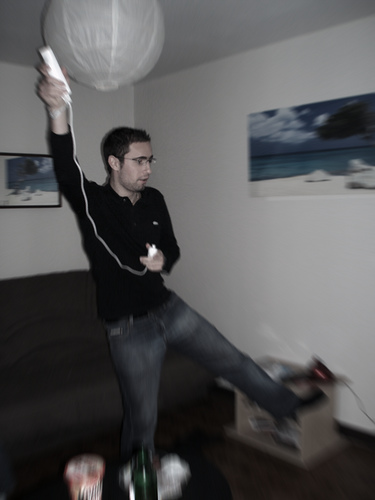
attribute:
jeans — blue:
[87, 289, 316, 486]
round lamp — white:
[39, 0, 170, 89]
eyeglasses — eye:
[115, 155, 157, 165]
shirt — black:
[43, 123, 180, 321]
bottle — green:
[129, 442, 156, 498]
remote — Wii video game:
[33, 42, 75, 108]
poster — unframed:
[245, 89, 374, 197]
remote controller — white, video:
[40, 46, 158, 275]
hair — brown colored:
[98, 125, 150, 169]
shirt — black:
[51, 132, 171, 307]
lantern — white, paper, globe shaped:
[36, 3, 172, 97]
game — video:
[40, 43, 160, 275]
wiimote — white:
[37, 44, 72, 95]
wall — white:
[126, 14, 373, 429]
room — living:
[12, 116, 363, 491]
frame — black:
[0, 153, 61, 207]